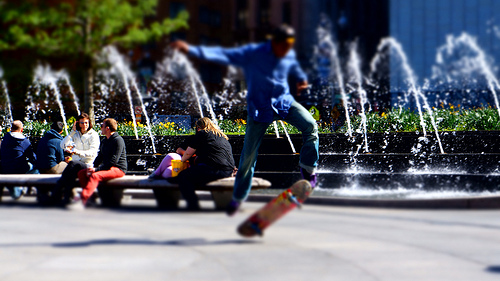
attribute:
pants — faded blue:
[232, 100, 322, 207]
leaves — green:
[52, 18, 93, 55]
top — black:
[103, 128, 132, 167]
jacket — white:
[56, 119, 119, 174]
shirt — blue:
[222, 43, 306, 116]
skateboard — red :
[240, 184, 313, 240]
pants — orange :
[84, 167, 125, 202]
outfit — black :
[160, 130, 233, 193]